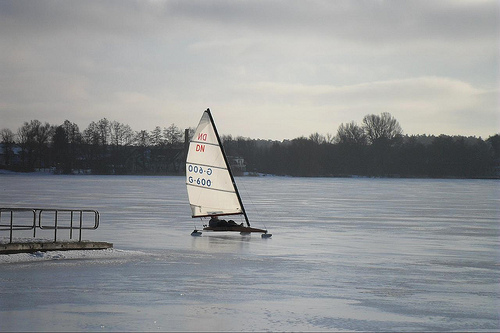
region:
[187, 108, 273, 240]
Sailboat on the water.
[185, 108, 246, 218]
Sail portion of boat on water.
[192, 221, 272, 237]
Boat sailing on the water.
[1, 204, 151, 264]
Metal and concrete dock.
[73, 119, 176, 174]
Bare trees lining the water.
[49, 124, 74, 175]
Evergreen tree lining the lake.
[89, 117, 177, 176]
Bare trees off the lake.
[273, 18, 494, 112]
Cloudy and overcast sky.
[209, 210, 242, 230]
Man laying down on boat.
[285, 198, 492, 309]
Dark waters of the lake.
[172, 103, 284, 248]
sale board with white sail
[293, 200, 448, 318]
flat ice of frozen lake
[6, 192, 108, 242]
metal rails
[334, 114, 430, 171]
tree line in the distance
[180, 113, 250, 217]
white sail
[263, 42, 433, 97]
slightly overcast sky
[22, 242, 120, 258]
grey cement dock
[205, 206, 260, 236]
man laying on sail board shadowed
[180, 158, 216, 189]
blue lettering on white sail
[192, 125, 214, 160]
red lettering on white sail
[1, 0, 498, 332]
an ice sailing craft on a frozen lake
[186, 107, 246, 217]
an ice craft with a white sail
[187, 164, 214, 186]
the identification numbers are printed on the sail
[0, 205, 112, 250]
a handrail and sidewalk leading to the lake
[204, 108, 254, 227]
the sail mast is black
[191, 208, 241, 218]
the sails boom is black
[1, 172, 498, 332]
the lake is frozen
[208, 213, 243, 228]
the sailor is laying down on the deck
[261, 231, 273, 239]
the ice sailing boats sleds slide on the ice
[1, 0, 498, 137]
grey cloudy skies mean a cold day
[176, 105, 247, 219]
the sail attached to the surfboard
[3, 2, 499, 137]
the cloudy sky above above the water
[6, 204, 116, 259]
a walkway by the water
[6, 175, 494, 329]
the water of the lake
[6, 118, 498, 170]
the line of trees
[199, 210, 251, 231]
a person laying on the surfboard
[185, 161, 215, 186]
writing on the sail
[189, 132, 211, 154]
some more writing on the sail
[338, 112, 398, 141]
trees standing above the rest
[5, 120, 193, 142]
some of the taller trees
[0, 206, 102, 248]
metal railing on the shore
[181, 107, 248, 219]
a white sail on the boat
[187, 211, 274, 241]
the deck of the small sailboat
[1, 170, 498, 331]
a pale blue lake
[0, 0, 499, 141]
a cloudy gray sky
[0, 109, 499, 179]
a row of trees behind the lake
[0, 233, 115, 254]
a cement slab on the shore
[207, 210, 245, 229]
a person on the sailboat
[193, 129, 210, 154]
red letters on the sail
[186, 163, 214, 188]
blue writing on the sail